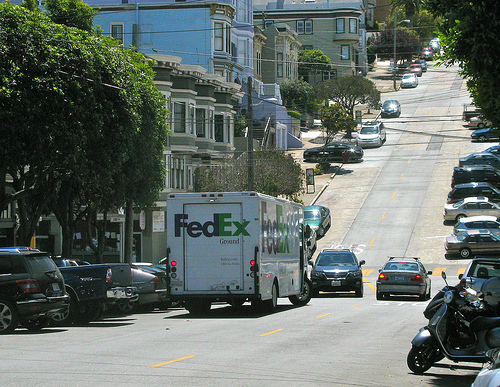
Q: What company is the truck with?
A: FedEx.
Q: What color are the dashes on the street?
A: Yellow.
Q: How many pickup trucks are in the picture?
A: One.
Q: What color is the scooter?
A: Black.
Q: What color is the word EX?
A: Green.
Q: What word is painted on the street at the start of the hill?
A: Stop.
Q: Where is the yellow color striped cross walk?
A: Bottom of hill.